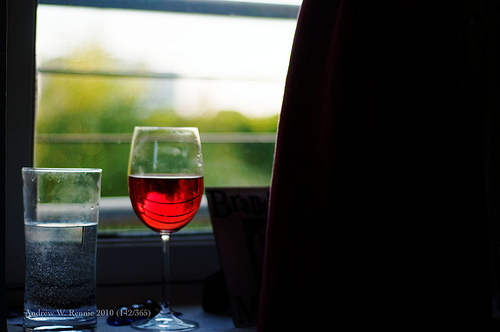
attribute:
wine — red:
[127, 174, 204, 230]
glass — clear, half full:
[128, 126, 206, 331]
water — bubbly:
[24, 221, 99, 321]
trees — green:
[35, 42, 281, 187]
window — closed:
[32, 3, 304, 241]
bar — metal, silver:
[34, 194, 137, 225]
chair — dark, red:
[255, 1, 500, 332]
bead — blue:
[114, 306, 132, 327]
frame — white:
[204, 186, 271, 331]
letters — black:
[211, 187, 269, 218]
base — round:
[133, 309, 200, 332]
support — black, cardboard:
[200, 269, 231, 318]